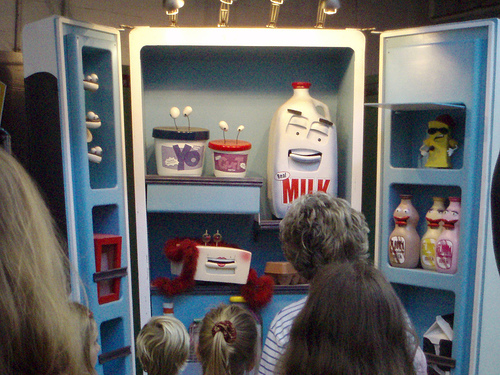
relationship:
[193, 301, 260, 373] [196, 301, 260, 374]
girl has hair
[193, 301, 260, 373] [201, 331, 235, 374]
girl has ponytail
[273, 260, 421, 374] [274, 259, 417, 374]
girl has hair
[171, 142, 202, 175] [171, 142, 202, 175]
word spells word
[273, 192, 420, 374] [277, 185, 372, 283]
girl has hair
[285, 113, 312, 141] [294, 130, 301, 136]
eye has pupil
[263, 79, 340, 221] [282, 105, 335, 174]
milk carton has face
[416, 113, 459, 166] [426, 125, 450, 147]
mustard bottle has face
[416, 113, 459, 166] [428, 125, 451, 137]
mustard bottle wears sunglasses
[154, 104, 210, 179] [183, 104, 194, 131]
yogurt container has eye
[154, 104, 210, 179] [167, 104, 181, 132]
yogurt container has eye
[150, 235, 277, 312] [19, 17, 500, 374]
scarf in refrigerator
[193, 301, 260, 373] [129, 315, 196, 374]
girl next to boy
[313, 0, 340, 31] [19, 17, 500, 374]
light on top of refrigerator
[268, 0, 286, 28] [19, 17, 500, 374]
light on top of refrigerator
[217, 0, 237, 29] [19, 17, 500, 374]
light on top of refrigerator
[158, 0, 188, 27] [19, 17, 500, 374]
light on top of refrigerator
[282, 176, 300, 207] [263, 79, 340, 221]
letter on milk carton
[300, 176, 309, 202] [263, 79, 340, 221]
letter on milk carton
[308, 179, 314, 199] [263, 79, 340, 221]
letter on milk carton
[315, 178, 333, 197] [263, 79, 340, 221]
letter on milk carton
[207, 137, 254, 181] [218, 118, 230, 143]
container has eyeball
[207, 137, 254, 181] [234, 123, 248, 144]
container has eyeball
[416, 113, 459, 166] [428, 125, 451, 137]
mustard bottle wears glasses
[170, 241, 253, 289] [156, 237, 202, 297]
toaster has arm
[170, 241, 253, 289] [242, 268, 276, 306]
toaster has arm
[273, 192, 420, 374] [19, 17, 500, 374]
girl looks at refrigerator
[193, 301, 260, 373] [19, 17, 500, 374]
girl looks at refrigerator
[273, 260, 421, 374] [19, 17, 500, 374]
girl looks at refrigerator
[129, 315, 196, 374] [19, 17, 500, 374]
boy looks at refrigerator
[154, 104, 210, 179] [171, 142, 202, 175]
yogurt container says word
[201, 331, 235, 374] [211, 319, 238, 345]
ponytail in holder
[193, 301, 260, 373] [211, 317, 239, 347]
girl has hair scrunchie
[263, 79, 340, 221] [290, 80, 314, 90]
milk carton has top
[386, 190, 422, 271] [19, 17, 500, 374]
bottle in refrigerator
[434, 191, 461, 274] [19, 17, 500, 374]
bottle in refrigerator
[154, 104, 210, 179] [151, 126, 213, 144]
yogurt container has lid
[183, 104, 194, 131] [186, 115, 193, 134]
eye on stick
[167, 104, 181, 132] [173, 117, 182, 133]
eye on stick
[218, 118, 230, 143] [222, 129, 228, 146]
eyeball on stick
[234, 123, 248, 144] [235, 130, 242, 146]
eyeball on stick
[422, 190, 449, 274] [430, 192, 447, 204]
bottle has lid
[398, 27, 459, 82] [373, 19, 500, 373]
light on door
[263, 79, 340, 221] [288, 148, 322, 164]
milk carton has mouth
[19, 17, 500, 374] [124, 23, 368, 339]
refrigerator has edge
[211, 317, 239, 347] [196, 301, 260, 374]
hair scrunchie in hair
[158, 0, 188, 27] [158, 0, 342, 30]
light in row of lights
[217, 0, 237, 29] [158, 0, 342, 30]
light in row of lights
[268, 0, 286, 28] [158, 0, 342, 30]
light in row of lights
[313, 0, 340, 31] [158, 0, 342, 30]
light in row of lights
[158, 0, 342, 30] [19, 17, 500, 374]
row of lights over refrigerator